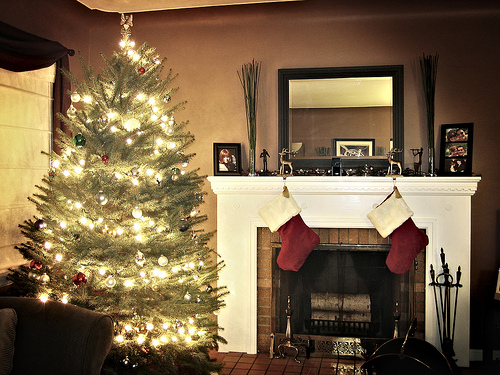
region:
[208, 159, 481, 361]
the fireplace is white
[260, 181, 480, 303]
stockings are red and white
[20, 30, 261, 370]
the tree has christmas lights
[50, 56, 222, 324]
tree has green and red ornaments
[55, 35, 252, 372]
lights on tree turned on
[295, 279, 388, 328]
wood in the fireplace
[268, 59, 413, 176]
mirror hung above fireplace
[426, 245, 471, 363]
fireplace metal sticks next to fireplace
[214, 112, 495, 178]
picture frames on fireplace mantle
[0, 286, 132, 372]
couch next to tree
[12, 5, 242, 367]
Christmas tree lit with white lights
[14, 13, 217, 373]
decorated christmas tree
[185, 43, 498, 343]
decorated fireplace mantle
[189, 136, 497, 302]
stocking hung on the mantle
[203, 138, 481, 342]
Red and white stockings hung on the fireplace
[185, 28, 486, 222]
Mirror hanging over the fireplace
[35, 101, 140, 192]
red and green christmas balls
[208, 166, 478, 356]
logs in the fireplace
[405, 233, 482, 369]
fireplace tools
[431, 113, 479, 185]
Framed family photos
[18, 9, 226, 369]
Illuminated Christmas tree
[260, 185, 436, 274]
Stockings hanging on the fireplace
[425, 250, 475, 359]
Pokers and items used for the fireplace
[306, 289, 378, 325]
Wooden logs in the fireplace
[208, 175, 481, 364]
Fireplace with a white mantle and Christmas stockings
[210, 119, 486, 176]
Pictures and items on the mantle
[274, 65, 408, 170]
Mirror mounted to the wall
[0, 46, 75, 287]
Window with brown drapes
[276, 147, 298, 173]
A reindeer statue on the mantle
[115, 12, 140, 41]
And angel on top of the Christmas tree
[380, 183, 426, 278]
red and white stocking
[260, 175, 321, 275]
red and white stocking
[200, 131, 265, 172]
picture on fire place mantle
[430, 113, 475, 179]
picture on fire place mantle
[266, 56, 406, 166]
mirror on fire place mantle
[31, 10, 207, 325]
tall green christmas tree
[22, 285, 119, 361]
big brown couch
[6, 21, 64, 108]
brown curtain on window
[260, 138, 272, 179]
black statue on mantle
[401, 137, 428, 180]
statue on white mantle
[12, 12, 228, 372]
Christmas tree in living room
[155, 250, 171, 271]
White ornament on Christmas tree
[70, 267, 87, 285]
Red ornament on Christmas tree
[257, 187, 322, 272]
Red and white Christmas stocking hung on fireplace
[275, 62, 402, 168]
Brown framed mirror over fireplace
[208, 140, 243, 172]
Framed photo of lady on fireplace mantel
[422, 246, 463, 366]
Metal fireplace tools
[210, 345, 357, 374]
Red bricks in front of fireplace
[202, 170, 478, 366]
White framed fireplace in living room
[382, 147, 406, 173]
Deer figurine on fireplace mantel